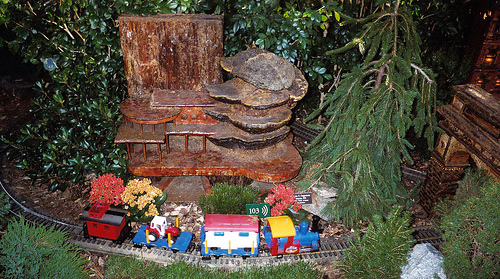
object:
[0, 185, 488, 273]
tracks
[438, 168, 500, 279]
bushes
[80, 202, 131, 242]
caboose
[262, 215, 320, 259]
engine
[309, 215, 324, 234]
smokestack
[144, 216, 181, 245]
tractor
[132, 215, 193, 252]
car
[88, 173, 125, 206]
flowers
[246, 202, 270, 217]
sign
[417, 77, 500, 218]
tunnel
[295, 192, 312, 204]
sign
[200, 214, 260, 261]
car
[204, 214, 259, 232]
roof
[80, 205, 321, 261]
train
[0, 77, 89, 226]
mulch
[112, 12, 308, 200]
decoration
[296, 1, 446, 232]
branch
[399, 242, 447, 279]
rock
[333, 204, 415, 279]
bushes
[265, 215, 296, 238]
roof